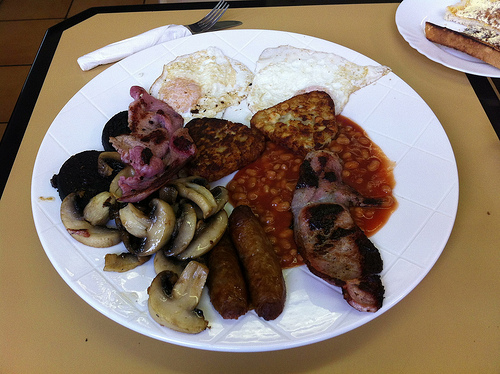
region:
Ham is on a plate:
[290, 141, 390, 312]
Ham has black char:
[285, 141, 392, 311]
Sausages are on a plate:
[190, 200, 291, 320]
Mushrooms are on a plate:
[50, 175, 231, 332]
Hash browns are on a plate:
[177, 87, 342, 179]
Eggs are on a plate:
[142, 45, 389, 120]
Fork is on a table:
[60, 0, 230, 70]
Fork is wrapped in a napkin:
[71, 0, 231, 70]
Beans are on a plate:
[223, 108, 398, 268]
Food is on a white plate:
[24, 20, 462, 360]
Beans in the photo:
[340, 148, 385, 187]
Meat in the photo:
[302, 205, 382, 274]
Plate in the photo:
[410, 172, 449, 242]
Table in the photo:
[413, 289, 483, 356]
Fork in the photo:
[72, 2, 246, 67]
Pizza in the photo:
[259, 89, 338, 148]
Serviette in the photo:
[62, 20, 189, 60]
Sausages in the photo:
[212, 239, 284, 320]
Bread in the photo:
[425, 6, 491, 48]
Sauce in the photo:
[261, 188, 295, 254]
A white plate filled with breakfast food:
[27, 25, 461, 352]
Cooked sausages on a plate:
[197, 209, 284, 326]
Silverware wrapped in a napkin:
[70, 0, 240, 72]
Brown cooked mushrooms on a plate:
[70, 178, 215, 330]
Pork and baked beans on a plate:
[252, 150, 402, 310]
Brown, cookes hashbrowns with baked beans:
[177, 87, 340, 182]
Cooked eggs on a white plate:
[147, 41, 386, 122]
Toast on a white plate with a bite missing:
[410, 0, 495, 77]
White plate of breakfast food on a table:
[9, 7, 496, 364]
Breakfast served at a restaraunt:
[5, 6, 496, 362]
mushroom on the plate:
[143, 268, 208, 328]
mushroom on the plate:
[123, 213, 172, 253]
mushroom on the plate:
[49, 186, 109, 248]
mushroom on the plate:
[184, 238, 210, 263]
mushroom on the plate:
[174, 173, 216, 220]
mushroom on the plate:
[145, 215, 172, 243]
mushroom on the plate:
[98, 155, 127, 197]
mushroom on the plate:
[102, 252, 144, 268]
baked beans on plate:
[251, 168, 268, 186]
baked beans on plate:
[361, 165, 378, 190]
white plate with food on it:
[40, 23, 442, 340]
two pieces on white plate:
[203, 206, 283, 318]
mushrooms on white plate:
[61, 178, 220, 320]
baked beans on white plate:
[230, 119, 400, 245]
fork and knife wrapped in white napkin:
[64, 5, 246, 57]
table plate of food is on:
[5, 16, 498, 368]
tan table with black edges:
[0, 2, 498, 350]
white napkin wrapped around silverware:
[72, 17, 182, 65]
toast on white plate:
[394, 4, 498, 88]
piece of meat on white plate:
[282, 150, 382, 298]